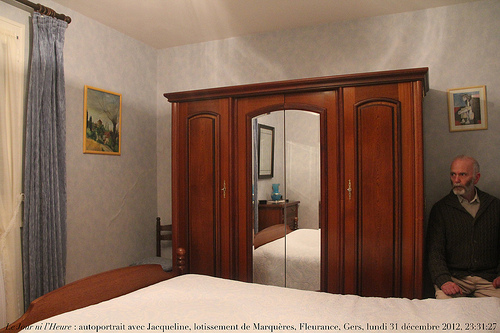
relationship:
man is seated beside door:
[424, 153, 496, 298] [336, 80, 421, 298]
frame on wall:
[83, 82, 123, 160] [65, 9, 155, 279]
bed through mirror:
[244, 229, 321, 294] [245, 104, 326, 290]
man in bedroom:
[428, 154, 500, 299] [2, 2, 484, 329]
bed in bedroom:
[2, 264, 500, 333] [2, 2, 484, 329]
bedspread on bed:
[20, 272, 484, 331] [2, 243, 484, 329]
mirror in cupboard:
[251, 109, 321, 292] [158, 63, 428, 302]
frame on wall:
[83, 84, 123, 155] [1, 0, 155, 331]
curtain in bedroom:
[23, 10, 68, 313] [2, 2, 484, 329]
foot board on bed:
[3, 245, 190, 331] [2, 243, 484, 329]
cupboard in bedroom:
[159, 67, 429, 299] [0, 2, 500, 330]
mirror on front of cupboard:
[232, 96, 332, 295] [159, 67, 429, 299]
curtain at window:
[21, 12, 71, 322] [2, 19, 22, 304]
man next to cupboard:
[428, 154, 500, 299] [159, 67, 429, 299]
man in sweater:
[428, 154, 500, 299] [423, 186, 483, 288]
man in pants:
[428, 154, 500, 299] [432, 275, 484, 300]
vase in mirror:
[268, 179, 284, 202] [241, 101, 329, 293]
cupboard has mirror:
[159, 67, 429, 299] [241, 101, 329, 293]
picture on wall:
[442, 84, 484, 132] [153, 5, 483, 294]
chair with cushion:
[127, 215, 175, 274] [126, 255, 175, 270]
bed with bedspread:
[2, 243, 484, 329] [19, 273, 500, 332]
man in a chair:
[428, 154, 500, 299] [433, 278, 490, 330]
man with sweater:
[428, 154, 500, 299] [428, 191, 490, 268]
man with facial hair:
[428, 154, 500, 299] [445, 180, 470, 195]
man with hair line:
[428, 154, 500, 299] [455, 157, 475, 167]